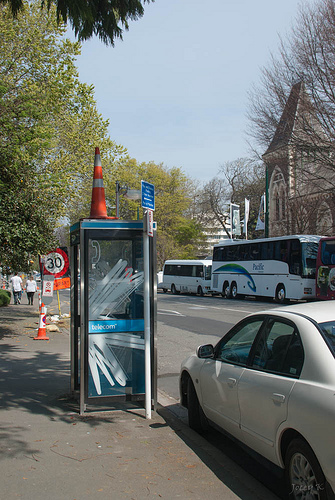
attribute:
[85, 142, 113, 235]
cone — orange, white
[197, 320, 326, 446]
car — white, parked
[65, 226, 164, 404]
telephone booth — blue, white, public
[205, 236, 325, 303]
bus — parked, large, white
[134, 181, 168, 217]
sign — tall, white, blue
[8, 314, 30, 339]
leaves — green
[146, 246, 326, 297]
buses — white, parked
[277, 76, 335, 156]
steeple — tall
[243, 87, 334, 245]
building — brick, church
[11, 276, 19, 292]
shirt — white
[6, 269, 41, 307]
people — walking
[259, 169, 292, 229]
windows — gothic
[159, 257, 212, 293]
bus — red, small, white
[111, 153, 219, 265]
tree — green, large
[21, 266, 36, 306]
woman — walking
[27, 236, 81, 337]
traffic signs — grouped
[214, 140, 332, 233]
church — brown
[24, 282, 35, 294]
tee shirt — white